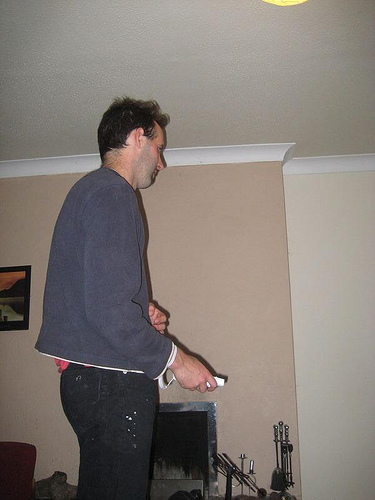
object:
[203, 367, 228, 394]
controller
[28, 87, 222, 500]
man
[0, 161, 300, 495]
wall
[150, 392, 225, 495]
fireplace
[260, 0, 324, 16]
light